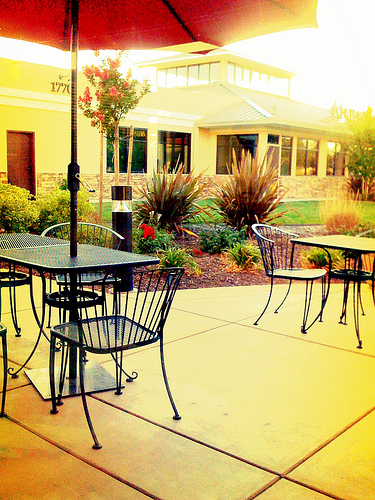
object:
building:
[0, 41, 375, 208]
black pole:
[68, 0, 80, 258]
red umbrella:
[0, 0, 318, 52]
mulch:
[0, 223, 335, 295]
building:
[1, 35, 366, 246]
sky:
[0, 1, 375, 115]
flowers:
[140, 220, 158, 240]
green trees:
[78, 51, 149, 182]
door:
[6, 130, 35, 196]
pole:
[111, 185, 135, 291]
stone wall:
[0, 59, 342, 200]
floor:
[0, 264, 372, 500]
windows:
[157, 129, 192, 174]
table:
[0, 241, 158, 288]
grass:
[92, 195, 375, 236]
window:
[296, 137, 319, 176]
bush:
[0, 177, 95, 235]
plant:
[128, 154, 218, 240]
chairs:
[329, 228, 373, 350]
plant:
[158, 246, 203, 277]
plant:
[199, 223, 248, 253]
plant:
[303, 244, 344, 269]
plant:
[318, 189, 364, 239]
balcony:
[135, 40, 295, 100]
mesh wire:
[58, 320, 156, 351]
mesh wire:
[57, 271, 115, 280]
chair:
[250, 222, 328, 332]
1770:
[50, 75, 70, 95]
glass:
[297, 136, 319, 176]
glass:
[157, 130, 191, 175]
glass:
[218, 135, 254, 175]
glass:
[326, 142, 347, 178]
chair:
[48, 262, 186, 450]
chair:
[39, 219, 126, 335]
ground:
[1, 200, 375, 497]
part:
[84, 245, 130, 274]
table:
[0, 232, 160, 401]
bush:
[203, 142, 295, 235]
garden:
[0, 197, 375, 293]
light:
[110, 200, 133, 212]